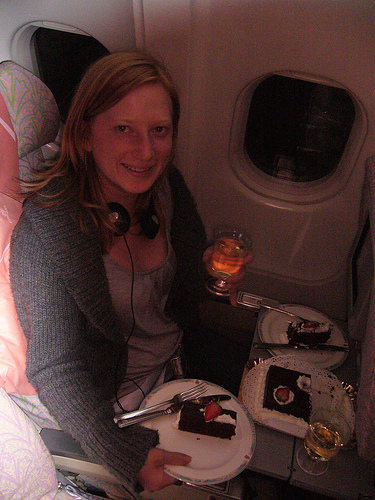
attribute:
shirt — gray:
[89, 173, 185, 403]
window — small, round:
[255, 61, 352, 189]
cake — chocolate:
[158, 377, 269, 458]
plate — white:
[130, 378, 259, 483]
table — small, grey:
[243, 297, 365, 498]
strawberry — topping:
[202, 394, 222, 428]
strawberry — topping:
[277, 383, 291, 401]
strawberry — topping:
[301, 317, 316, 332]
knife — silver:
[252, 296, 324, 329]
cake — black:
[256, 369, 323, 435]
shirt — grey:
[131, 268, 188, 355]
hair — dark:
[28, 56, 175, 214]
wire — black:
[117, 235, 138, 343]